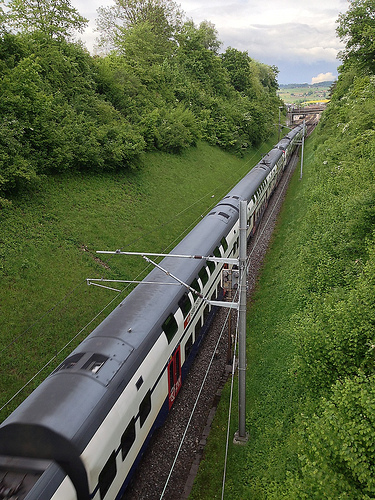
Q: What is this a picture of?
A: Train.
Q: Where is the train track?
A: Under the train.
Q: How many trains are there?
A: 1.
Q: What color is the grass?
A: Green.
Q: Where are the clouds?
A: In the sky.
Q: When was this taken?
A: Daytime.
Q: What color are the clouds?
A: White.